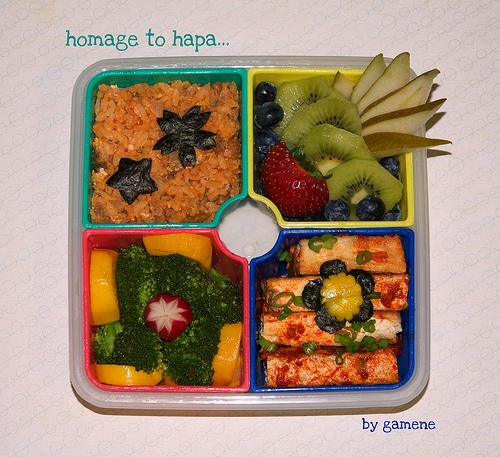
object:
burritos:
[288, 235, 405, 277]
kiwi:
[296, 124, 375, 178]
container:
[248, 67, 415, 226]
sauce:
[218, 200, 282, 264]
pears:
[356, 51, 408, 117]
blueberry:
[379, 156, 401, 178]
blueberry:
[356, 195, 386, 221]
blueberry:
[324, 199, 351, 221]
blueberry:
[253, 102, 283, 129]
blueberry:
[254, 81, 278, 105]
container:
[64, 55, 434, 417]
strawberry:
[255, 134, 333, 219]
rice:
[90, 81, 243, 227]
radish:
[144, 290, 194, 342]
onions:
[378, 337, 390, 348]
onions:
[335, 356, 343, 365]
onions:
[303, 341, 318, 356]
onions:
[256, 337, 277, 353]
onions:
[346, 340, 360, 352]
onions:
[363, 319, 375, 333]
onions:
[355, 249, 371, 264]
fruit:
[252, 49, 453, 221]